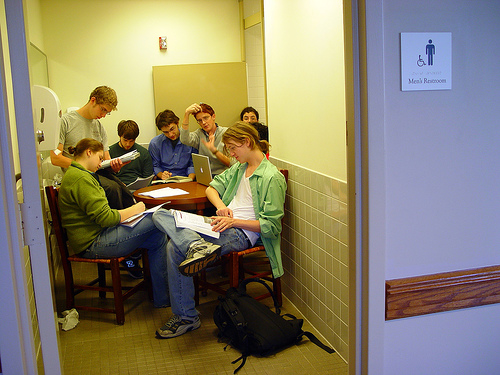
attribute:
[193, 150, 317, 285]
shirt — green, long sleeve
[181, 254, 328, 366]
backpack — black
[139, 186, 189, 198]
book — white, open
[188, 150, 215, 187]
laptop — Grey 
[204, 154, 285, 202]
shirt — white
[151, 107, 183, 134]
hair — dark brown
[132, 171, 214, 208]
table. — round, wooden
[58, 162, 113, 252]
sweater — green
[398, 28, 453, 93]
sign — bathroom,  handicap symbol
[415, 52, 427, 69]
handicap symbol — handicap 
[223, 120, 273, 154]
hair — dirty blonde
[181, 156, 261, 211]
laptop — SILVER, APPLE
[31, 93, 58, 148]
dispenser — white, paper towel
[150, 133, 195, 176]
shirt — blue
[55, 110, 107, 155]
t-shirt — grey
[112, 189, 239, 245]
book — open